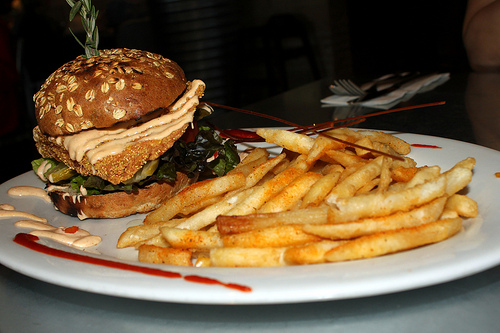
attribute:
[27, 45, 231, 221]
sandwich — green, large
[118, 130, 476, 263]
fries — cut, golden, fresh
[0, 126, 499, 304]
plate — white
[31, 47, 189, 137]
bun — seedy, wheat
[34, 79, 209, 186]
meat — breaded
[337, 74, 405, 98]
fork — behind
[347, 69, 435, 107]
knife — behind